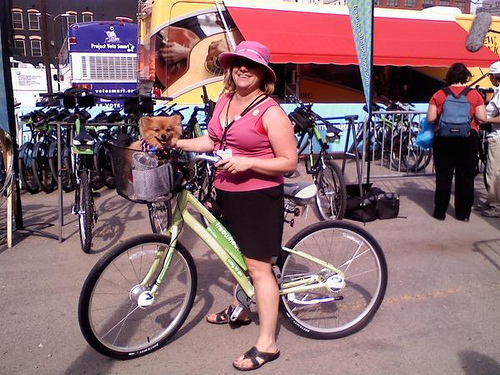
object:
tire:
[77, 233, 197, 361]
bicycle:
[287, 104, 347, 223]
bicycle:
[39, 87, 109, 253]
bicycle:
[369, 102, 424, 172]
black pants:
[431, 135, 477, 220]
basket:
[102, 139, 177, 204]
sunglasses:
[233, 58, 259, 66]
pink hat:
[239, 40, 258, 50]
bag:
[344, 183, 408, 225]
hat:
[218, 39, 276, 85]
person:
[426, 62, 487, 221]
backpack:
[440, 86, 471, 136]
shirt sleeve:
[428, 85, 484, 133]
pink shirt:
[208, 90, 285, 192]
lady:
[177, 41, 299, 372]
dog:
[124, 114, 184, 178]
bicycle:
[76, 140, 389, 361]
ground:
[0, 158, 500, 375]